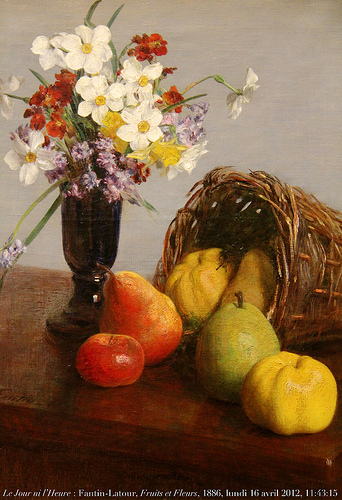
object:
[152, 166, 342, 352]
basket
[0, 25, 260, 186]
daisy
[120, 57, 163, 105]
daisy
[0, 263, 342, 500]
table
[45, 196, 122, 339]
vase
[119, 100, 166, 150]
flower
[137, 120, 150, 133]
yellow middle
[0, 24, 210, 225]
many colors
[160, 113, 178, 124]
pink flower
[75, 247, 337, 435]
fruit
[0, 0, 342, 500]
painting